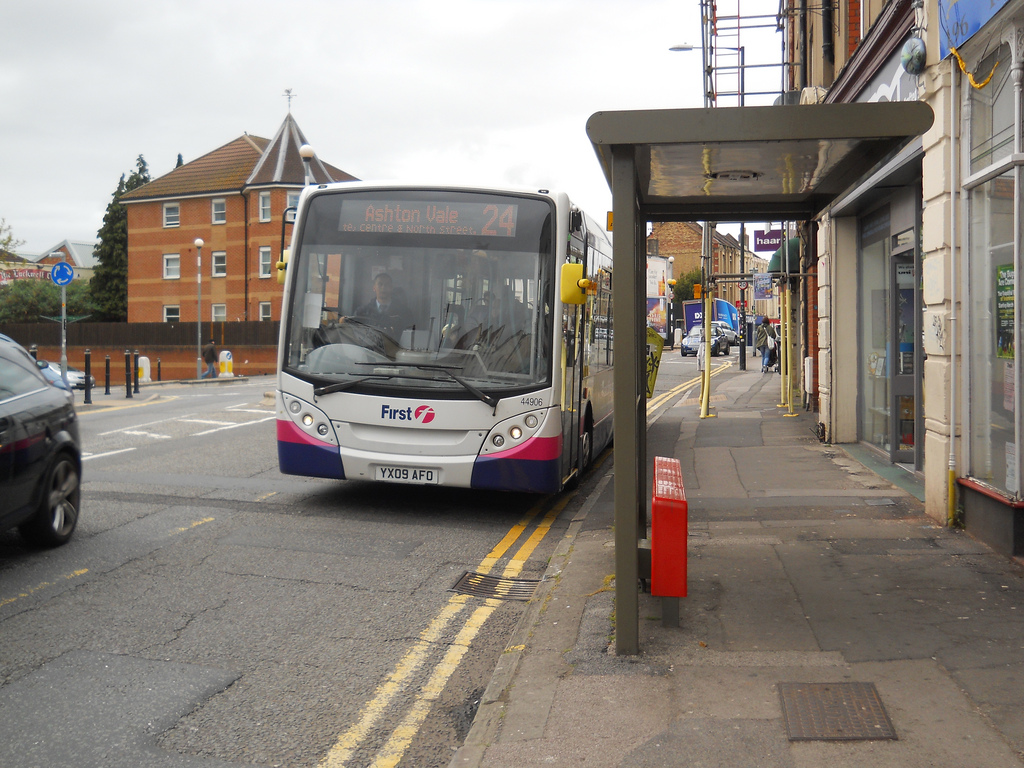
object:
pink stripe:
[532, 437, 559, 458]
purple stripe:
[479, 461, 557, 490]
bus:
[274, 177, 614, 496]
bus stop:
[584, 98, 932, 661]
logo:
[373, 390, 441, 425]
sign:
[46, 242, 88, 290]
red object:
[652, 455, 690, 599]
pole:
[616, 538, 637, 590]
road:
[0, 313, 728, 766]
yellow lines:
[256, 354, 744, 765]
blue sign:
[936, 0, 1008, 57]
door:
[955, 177, 1023, 529]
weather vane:
[283, 87, 298, 112]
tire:
[22, 447, 81, 550]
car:
[0, 336, 84, 565]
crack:
[2, 632, 98, 686]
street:
[0, 333, 738, 762]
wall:
[121, 208, 160, 321]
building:
[107, 123, 363, 334]